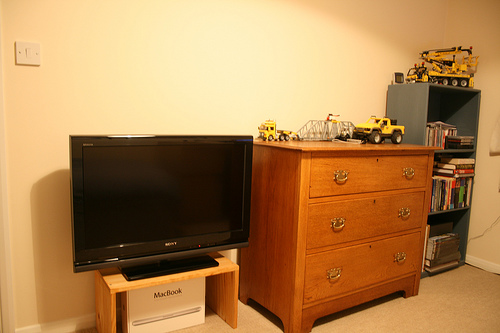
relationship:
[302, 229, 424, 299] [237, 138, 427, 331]
drawer on furniture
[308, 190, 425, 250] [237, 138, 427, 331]
drawer on furniture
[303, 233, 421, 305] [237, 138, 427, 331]
drawer on furniture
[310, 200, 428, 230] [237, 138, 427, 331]
drawer on furniture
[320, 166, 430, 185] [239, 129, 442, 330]
drawer on furniture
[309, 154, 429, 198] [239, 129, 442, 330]
drawer on furniture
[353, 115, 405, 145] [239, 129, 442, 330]
toy truck on furniture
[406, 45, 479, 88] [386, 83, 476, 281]
truck on bookshelf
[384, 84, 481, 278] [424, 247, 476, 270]
book shelf has shelf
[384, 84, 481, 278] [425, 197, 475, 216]
book shelf has shelf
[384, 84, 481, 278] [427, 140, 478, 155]
book shelf has shelf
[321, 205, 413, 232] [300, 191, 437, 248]
handles fixed to draw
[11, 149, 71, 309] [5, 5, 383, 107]
shadow falling on wall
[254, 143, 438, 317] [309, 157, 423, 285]
furniture with draws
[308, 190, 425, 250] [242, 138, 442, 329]
drawer on chest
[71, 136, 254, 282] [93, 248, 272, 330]
television on stand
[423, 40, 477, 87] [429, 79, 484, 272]
truck on dresser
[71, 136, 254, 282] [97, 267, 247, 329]
television on a stand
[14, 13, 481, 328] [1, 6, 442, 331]
room with wall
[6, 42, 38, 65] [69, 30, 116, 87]
board fixed on wall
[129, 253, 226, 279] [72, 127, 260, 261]
stand on television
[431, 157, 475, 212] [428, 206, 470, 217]
books arrange on shelf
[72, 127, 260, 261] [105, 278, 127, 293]
television on table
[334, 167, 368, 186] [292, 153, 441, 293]
handles on chest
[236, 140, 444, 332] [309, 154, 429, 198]
chest of drawer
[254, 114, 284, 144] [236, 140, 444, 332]
truck on top chest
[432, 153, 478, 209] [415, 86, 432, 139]
books on shelf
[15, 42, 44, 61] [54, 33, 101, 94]
plate on wall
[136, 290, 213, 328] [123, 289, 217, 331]
laptop on front box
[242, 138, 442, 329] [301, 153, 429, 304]
chest of drawers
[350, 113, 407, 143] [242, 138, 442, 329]
toy truck on chest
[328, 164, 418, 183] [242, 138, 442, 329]
knobs of chest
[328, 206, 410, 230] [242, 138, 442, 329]
knobs of chest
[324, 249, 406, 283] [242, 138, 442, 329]
knobs of chest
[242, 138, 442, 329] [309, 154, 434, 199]
chest has drawer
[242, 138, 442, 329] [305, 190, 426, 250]
chest has drawer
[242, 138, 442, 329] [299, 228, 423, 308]
chest has drawer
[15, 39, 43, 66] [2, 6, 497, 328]
light switch on wall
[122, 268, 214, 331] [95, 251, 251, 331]
box under stand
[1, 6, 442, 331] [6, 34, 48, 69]
wall on light switch